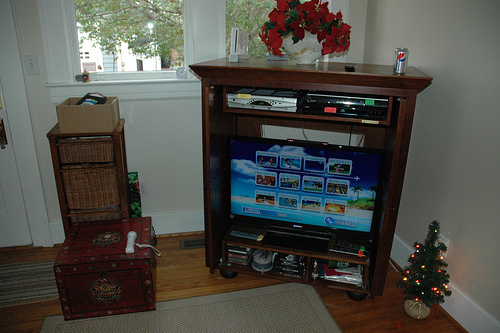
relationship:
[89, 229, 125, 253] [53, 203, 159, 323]
design on box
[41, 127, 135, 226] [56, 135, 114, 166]
shelf with baskets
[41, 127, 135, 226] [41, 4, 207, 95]
shelf near window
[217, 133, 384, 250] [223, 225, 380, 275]
tv on shelf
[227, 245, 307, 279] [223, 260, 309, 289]
cds on shelf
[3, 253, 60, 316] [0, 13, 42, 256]
mat by door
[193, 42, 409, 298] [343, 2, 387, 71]
stand in corner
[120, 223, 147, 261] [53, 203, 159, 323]
remote on box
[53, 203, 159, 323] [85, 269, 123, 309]
box has design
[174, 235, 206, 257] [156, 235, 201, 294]
vent in floor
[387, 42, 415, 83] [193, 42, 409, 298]
can on stand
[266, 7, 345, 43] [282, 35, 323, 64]
poinsettia in vase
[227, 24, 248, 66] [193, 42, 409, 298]
wii on stand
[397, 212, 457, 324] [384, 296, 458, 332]
tree on floor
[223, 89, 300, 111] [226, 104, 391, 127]
box on shelf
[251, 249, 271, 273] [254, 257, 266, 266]
cds in holder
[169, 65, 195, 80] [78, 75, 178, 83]
clock on sill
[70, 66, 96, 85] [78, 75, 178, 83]
decoration on sill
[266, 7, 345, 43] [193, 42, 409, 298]
poinsettia on stand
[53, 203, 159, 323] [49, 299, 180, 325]
box on floor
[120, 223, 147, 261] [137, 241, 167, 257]
remote has strap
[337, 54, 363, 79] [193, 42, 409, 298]
remote on stand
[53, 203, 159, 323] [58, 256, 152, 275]
box has border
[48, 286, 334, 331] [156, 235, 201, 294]
rug on floor